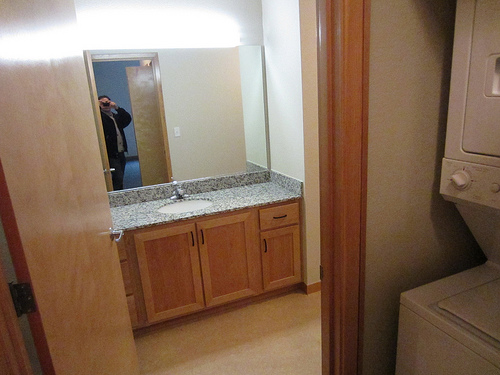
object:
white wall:
[261, 0, 320, 285]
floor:
[132, 292, 321, 375]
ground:
[133, 293, 318, 375]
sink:
[159, 199, 211, 213]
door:
[0, 0, 140, 375]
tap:
[170, 181, 188, 200]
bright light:
[0, 7, 262, 63]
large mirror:
[88, 43, 268, 192]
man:
[98, 95, 131, 191]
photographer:
[98, 95, 132, 190]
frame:
[316, 0, 369, 375]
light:
[72, 8, 240, 51]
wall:
[365, 1, 486, 375]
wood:
[320, 0, 371, 375]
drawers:
[258, 201, 300, 231]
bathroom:
[74, 0, 322, 375]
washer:
[396, 262, 499, 375]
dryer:
[394, 0, 500, 375]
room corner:
[357, 0, 500, 375]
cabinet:
[136, 202, 301, 325]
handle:
[190, 231, 195, 246]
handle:
[200, 230, 205, 245]